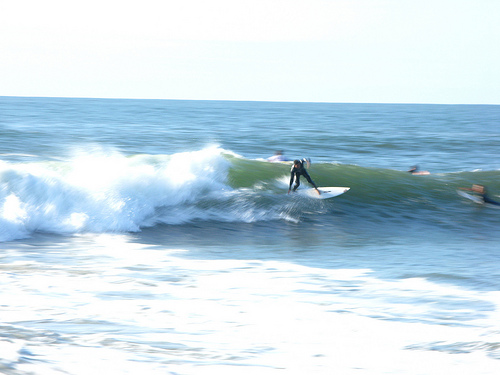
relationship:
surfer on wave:
[276, 156, 315, 192] [25, 129, 481, 242]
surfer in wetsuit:
[276, 156, 315, 192] [284, 167, 324, 189]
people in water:
[264, 156, 477, 209] [81, 248, 401, 296]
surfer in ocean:
[276, 156, 315, 192] [52, 86, 462, 160]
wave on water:
[25, 129, 481, 242] [81, 248, 401, 296]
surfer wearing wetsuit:
[276, 156, 315, 192] [284, 167, 324, 189]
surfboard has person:
[280, 188, 366, 206] [283, 150, 323, 196]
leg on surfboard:
[303, 175, 324, 195] [280, 188, 366, 206]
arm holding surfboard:
[286, 168, 293, 194] [280, 188, 366, 206]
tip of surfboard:
[340, 180, 358, 204] [280, 188, 366, 206]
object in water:
[398, 159, 422, 182] [81, 248, 401, 296]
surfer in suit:
[276, 156, 315, 192] [294, 168, 317, 188]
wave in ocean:
[25, 129, 481, 242] [52, 86, 462, 160]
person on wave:
[283, 150, 323, 196] [25, 129, 481, 242]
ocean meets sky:
[52, 86, 462, 160] [33, 6, 477, 100]